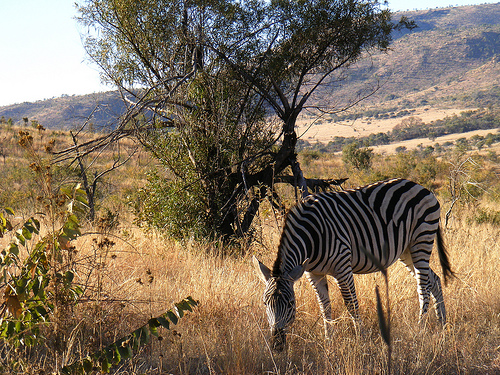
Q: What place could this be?
A: It is a field.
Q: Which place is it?
A: It is a field.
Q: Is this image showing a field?
A: Yes, it is showing a field.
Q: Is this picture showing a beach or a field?
A: It is showing a field.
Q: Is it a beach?
A: No, it is a field.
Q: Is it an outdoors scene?
A: Yes, it is outdoors.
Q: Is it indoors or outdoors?
A: It is outdoors.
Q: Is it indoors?
A: No, it is outdoors.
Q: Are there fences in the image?
A: No, there are no fences.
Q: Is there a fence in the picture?
A: No, there are no fences.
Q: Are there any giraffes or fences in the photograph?
A: No, there are no fences or giraffes.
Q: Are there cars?
A: No, there are no cars.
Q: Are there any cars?
A: No, there are no cars.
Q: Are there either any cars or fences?
A: No, there are no cars or fences.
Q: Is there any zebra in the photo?
A: Yes, there is a zebra.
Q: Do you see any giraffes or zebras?
A: Yes, there is a zebra.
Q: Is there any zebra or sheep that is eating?
A: Yes, the zebra is eating.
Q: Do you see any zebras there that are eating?
A: Yes, there is a zebra that is eating.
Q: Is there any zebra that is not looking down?
A: Yes, there is a zebra that is eating.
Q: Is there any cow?
A: No, there are no cows.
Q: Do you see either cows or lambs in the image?
A: No, there are no cows or lambs.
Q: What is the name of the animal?
A: The animal is a zebra.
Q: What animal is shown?
A: The animal is a zebra.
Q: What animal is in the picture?
A: The animal is a zebra.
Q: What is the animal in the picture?
A: The animal is a zebra.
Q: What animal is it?
A: The animal is a zebra.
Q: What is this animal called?
A: That is a zebra.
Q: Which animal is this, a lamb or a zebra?
A: That is a zebra.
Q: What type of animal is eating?
A: The animal is a zebra.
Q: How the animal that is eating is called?
A: The animal is a zebra.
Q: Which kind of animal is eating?
A: The animal is a zebra.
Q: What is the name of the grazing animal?
A: The animal is a zebra.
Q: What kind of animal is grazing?
A: The animal is a zebra.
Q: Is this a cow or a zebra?
A: This is a zebra.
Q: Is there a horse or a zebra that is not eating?
A: No, there is a zebra but it is eating.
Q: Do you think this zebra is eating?
A: Yes, the zebra is eating.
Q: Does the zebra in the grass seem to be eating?
A: Yes, the zebra is eating.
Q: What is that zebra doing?
A: The zebra is eating.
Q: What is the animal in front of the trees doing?
A: The zebra is eating.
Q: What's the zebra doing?
A: The zebra is eating.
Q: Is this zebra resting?
A: No, the zebra is eating.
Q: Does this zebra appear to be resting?
A: No, the zebra is eating.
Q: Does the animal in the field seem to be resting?
A: No, the zebra is eating.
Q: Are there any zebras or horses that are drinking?
A: No, there is a zebra but it is eating.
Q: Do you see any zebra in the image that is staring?
A: No, there is a zebra but it is eating.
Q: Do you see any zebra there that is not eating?
A: No, there is a zebra but it is eating.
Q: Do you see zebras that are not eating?
A: No, there is a zebra but it is eating.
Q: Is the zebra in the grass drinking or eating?
A: The zebra is eating.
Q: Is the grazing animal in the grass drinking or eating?
A: The zebra is eating.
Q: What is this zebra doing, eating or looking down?
A: The zebra is eating.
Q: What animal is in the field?
A: The animal is a zebra.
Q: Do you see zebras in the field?
A: Yes, there is a zebra in the field.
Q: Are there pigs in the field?
A: No, there is a zebra in the field.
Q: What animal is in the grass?
A: The zebra is in the grass.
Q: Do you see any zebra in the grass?
A: Yes, there is a zebra in the grass.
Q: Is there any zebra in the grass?
A: Yes, there is a zebra in the grass.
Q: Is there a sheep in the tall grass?
A: No, there is a zebra in the grass.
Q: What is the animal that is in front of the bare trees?
A: The animal is a zebra.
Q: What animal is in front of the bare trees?
A: The animal is a zebra.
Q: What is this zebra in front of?
A: The zebra is in front of the trees.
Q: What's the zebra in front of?
A: The zebra is in front of the trees.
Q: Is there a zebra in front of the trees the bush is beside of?
A: Yes, there is a zebra in front of the trees.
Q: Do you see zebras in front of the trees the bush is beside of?
A: Yes, there is a zebra in front of the trees.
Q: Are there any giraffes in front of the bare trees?
A: No, there is a zebra in front of the trees.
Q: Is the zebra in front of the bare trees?
A: Yes, the zebra is in front of the trees.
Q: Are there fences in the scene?
A: No, there are no fences.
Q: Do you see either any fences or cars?
A: No, there are no fences or cars.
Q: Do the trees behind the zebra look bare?
A: Yes, the trees are bare.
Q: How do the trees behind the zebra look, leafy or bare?
A: The trees are bare.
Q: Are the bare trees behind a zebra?
A: Yes, the trees are behind a zebra.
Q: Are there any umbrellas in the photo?
A: No, there are no umbrellas.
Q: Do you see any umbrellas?
A: No, there are no umbrellas.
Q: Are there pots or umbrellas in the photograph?
A: No, there are no umbrellas or pots.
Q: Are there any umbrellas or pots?
A: No, there are no umbrellas or pots.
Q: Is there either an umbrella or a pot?
A: No, there are no umbrellas or pots.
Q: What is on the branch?
A: The leaves are on the branch.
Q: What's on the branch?
A: The leaves are on the branch.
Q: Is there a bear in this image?
A: No, there are no bears.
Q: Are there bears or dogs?
A: No, there are no bears or dogs.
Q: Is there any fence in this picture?
A: No, there are no fences.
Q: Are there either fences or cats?
A: No, there are no fences or cats.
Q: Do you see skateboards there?
A: No, there are no skateboards.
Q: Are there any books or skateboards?
A: No, there are no skateboards or books.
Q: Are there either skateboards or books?
A: No, there are no skateboards or books.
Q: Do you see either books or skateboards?
A: No, there are no skateboards or books.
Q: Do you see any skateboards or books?
A: No, there are no skateboards or books.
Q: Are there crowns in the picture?
A: No, there are no crowns.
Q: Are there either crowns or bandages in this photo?
A: No, there are no crowns or bandages.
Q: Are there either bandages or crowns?
A: No, there are no crowns or bandages.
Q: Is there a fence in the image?
A: No, there are no fences.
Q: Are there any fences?
A: No, there are no fences.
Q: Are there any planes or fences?
A: No, there are no fences or planes.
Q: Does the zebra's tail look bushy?
A: Yes, the tail is bushy.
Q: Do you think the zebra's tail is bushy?
A: Yes, the tail is bushy.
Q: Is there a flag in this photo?
A: No, there are no flags.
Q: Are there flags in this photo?
A: No, there are no flags.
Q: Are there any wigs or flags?
A: No, there are no flags or wigs.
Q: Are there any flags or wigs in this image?
A: No, there are no flags or wigs.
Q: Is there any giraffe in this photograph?
A: No, there are no giraffes.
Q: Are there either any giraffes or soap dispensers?
A: No, there are no giraffes or soap dispensers.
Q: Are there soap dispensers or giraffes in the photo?
A: No, there are no giraffes or soap dispensers.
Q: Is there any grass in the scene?
A: Yes, there is grass.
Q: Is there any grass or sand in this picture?
A: Yes, there is grass.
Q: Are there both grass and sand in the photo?
A: No, there is grass but no sand.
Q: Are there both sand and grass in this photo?
A: No, there is grass but no sand.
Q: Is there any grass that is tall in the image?
A: Yes, there is tall grass.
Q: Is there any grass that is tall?
A: Yes, there is grass that is tall.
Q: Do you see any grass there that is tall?
A: Yes, there is grass that is tall.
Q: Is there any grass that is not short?
A: Yes, there is tall grass.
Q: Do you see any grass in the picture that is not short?
A: Yes, there is tall grass.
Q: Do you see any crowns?
A: No, there are no crowns.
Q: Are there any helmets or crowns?
A: No, there are no crowns or helmets.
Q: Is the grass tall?
A: Yes, the grass is tall.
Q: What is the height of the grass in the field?
A: The grass is tall.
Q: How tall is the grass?
A: The grass is tall.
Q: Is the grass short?
A: No, the grass is tall.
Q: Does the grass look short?
A: No, the grass is tall.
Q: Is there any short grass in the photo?
A: No, there is grass but it is tall.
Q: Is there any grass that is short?
A: No, there is grass but it is tall.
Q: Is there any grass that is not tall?
A: No, there is grass but it is tall.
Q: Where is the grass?
A: The grass is in the field.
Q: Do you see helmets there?
A: No, there are no helmets.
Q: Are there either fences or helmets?
A: No, there are no helmets or fences.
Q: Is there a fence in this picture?
A: No, there are no fences.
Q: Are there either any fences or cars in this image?
A: No, there are no fences or cars.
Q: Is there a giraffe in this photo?
A: No, there are no giraffes.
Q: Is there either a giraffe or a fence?
A: No, there are no giraffes or fences.